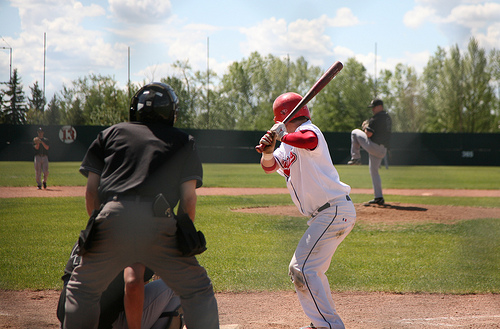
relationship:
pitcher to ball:
[346, 99, 388, 204] [362, 119, 369, 130]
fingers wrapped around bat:
[260, 136, 283, 146] [256, 73, 350, 144]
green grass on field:
[1, 190, 498, 305] [3, 115, 498, 327]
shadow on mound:
[385, 203, 431, 211] [223, 198, 497, 223]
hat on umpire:
[128, 81, 180, 126] [58, 80, 218, 323]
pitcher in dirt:
[347, 98, 393, 206] [247, 201, 492, 223]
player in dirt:
[29, 124, 51, 190] [4, 184, 495, 201]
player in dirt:
[58, 242, 177, 324] [0, 286, 488, 327]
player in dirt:
[72, 77, 216, 314] [0, 286, 488, 327]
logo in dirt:
[58, 125, 77, 144] [0, 286, 488, 327]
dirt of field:
[247, 201, 492, 223] [4, 166, 494, 324]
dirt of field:
[0, 286, 488, 327] [4, 166, 494, 324]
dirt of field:
[4, 184, 495, 201] [4, 166, 494, 324]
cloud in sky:
[0, 1, 498, 97] [282, 0, 407, 52]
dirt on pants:
[331, 227, 347, 245] [280, 216, 365, 326]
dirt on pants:
[288, 265, 309, 295] [280, 216, 365, 326]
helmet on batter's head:
[266, 90, 313, 124] [274, 93, 310, 135]